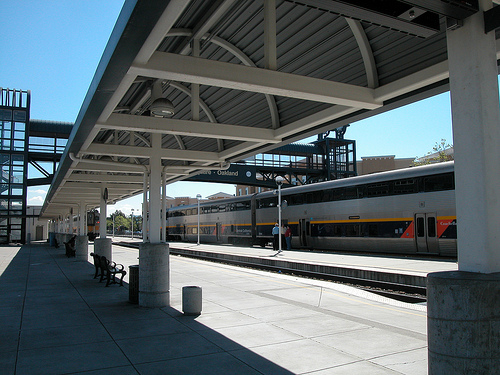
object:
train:
[147, 160, 455, 259]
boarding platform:
[78, 233, 438, 355]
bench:
[90, 253, 126, 286]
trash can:
[128, 265, 140, 304]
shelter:
[39, 0, 500, 222]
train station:
[2, 2, 496, 370]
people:
[272, 223, 279, 249]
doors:
[414, 211, 428, 252]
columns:
[136, 122, 169, 308]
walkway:
[0, 224, 467, 375]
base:
[139, 242, 172, 308]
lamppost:
[274, 175, 285, 256]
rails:
[113, 239, 428, 303]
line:
[309, 217, 413, 223]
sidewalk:
[14, 240, 209, 368]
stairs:
[0, 194, 25, 202]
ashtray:
[181, 286, 204, 315]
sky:
[0, 0, 499, 219]